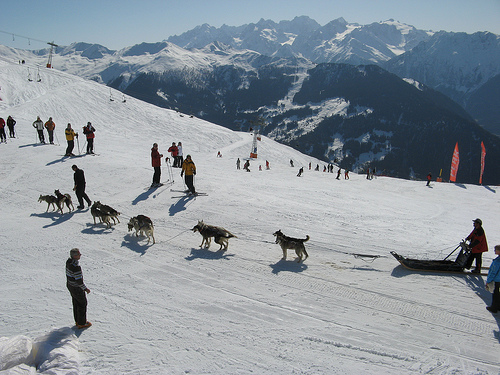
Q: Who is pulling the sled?
A: Dogs.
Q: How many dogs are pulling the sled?
A: Ten.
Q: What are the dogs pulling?
A: A sled.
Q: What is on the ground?
A: Snow.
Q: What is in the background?
A: Mountains.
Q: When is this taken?
A: Daytime.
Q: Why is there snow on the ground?
A: It is wintertime.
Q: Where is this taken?
A: A mountainside.